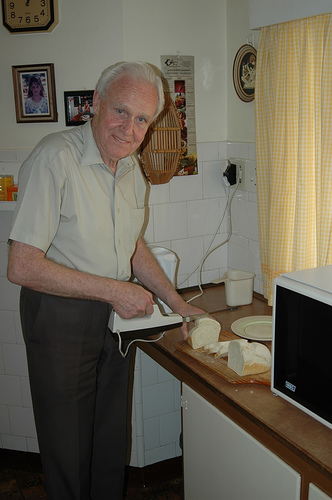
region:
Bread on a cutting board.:
[179, 306, 270, 377]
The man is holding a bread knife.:
[100, 292, 214, 338]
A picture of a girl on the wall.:
[1, 61, 66, 122]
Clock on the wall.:
[2, 0, 63, 35]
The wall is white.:
[65, 12, 138, 47]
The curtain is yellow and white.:
[265, 63, 324, 220]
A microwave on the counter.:
[255, 277, 331, 417]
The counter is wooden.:
[204, 293, 258, 318]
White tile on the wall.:
[159, 195, 211, 245]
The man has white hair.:
[84, 53, 172, 159]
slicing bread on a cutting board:
[146, 289, 267, 382]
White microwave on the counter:
[236, 254, 328, 424]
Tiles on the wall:
[146, 209, 272, 311]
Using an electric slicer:
[91, 287, 243, 358]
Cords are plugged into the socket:
[210, 135, 264, 220]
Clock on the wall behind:
[1, 1, 84, 55]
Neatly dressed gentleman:
[13, 42, 263, 473]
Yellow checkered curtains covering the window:
[236, 7, 331, 316]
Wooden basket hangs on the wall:
[124, 49, 232, 222]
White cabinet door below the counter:
[161, 365, 307, 496]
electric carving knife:
[106, 302, 247, 339]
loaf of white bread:
[226, 338, 272, 378]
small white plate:
[229, 312, 278, 344]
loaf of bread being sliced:
[173, 314, 247, 364]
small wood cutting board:
[179, 336, 274, 383]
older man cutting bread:
[17, 58, 145, 490]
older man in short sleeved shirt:
[6, 61, 167, 300]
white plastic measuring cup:
[209, 266, 256, 308]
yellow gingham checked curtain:
[250, 22, 331, 322]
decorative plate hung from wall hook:
[227, 36, 263, 104]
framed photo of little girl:
[6, 62, 62, 126]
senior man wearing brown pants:
[18, 51, 220, 498]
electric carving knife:
[106, 280, 219, 364]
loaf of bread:
[183, 304, 279, 387]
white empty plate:
[223, 313, 280, 347]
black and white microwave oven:
[266, 264, 328, 428]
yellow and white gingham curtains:
[255, 42, 330, 266]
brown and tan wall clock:
[1, 0, 65, 34]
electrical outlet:
[218, 145, 254, 203]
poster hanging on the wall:
[157, 45, 203, 185]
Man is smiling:
[0, 40, 183, 498]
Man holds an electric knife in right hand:
[0, 45, 217, 496]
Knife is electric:
[102, 279, 246, 349]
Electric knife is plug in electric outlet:
[100, 156, 252, 356]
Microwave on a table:
[267, 260, 330, 432]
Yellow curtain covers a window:
[232, 8, 330, 321]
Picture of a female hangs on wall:
[11, 56, 62, 127]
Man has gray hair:
[11, 44, 185, 204]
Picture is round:
[223, 36, 265, 105]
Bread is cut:
[166, 288, 272, 386]